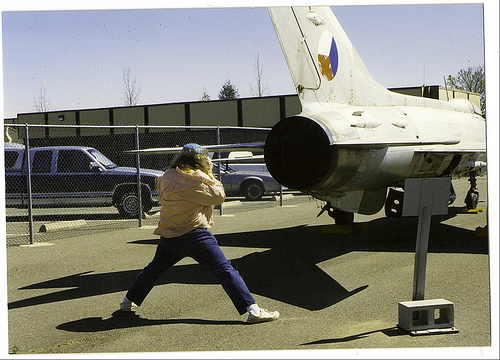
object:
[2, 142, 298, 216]
car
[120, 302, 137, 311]
sneakers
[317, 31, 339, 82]
emblem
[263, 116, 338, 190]
tail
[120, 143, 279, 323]
blonde person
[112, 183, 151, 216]
tire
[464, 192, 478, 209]
airplane wheel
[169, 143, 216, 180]
head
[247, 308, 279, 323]
shoe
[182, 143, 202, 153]
hat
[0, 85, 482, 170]
building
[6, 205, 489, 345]
shadow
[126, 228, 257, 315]
jeans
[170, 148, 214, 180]
hair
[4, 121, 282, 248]
fence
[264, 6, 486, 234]
jet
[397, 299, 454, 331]
block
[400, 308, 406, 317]
concrete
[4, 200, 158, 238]
parking lot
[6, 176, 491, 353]
ground